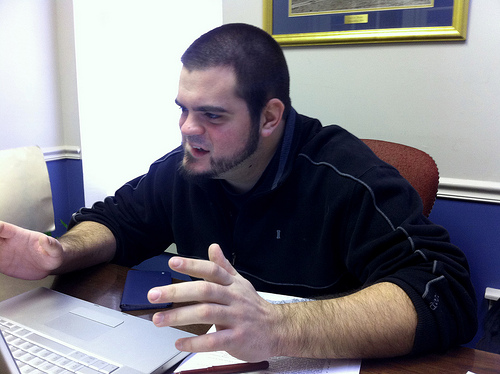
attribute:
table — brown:
[59, 244, 498, 372]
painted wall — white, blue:
[3, 2, 497, 349]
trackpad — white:
[43, 310, 201, 340]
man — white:
[45, 10, 472, 352]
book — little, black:
[97, 246, 205, 324]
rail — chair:
[43, 142, 498, 209]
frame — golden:
[275, 24, 458, 39]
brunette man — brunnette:
[83, 19, 383, 285]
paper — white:
[181, 287, 367, 372]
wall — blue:
[437, 201, 499, 331]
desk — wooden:
[14, 169, 499, 371]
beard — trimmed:
[175, 121, 276, 191]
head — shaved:
[175, 22, 290, 183]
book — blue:
[119, 265, 172, 311]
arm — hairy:
[146, 239, 476, 364]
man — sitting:
[17, 20, 471, 372]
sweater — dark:
[69, 129, 469, 346]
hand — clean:
[143, 242, 268, 363]